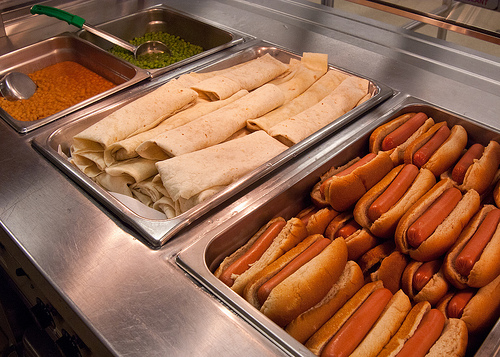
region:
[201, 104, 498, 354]
A lot of hot dogs.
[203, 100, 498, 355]
The hot dogs are in buns.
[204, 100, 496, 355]
The pan is made of metal.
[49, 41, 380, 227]
The wraps are made of bread.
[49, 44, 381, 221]
The wraps are white.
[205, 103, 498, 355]
The bread is brean.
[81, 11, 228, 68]
The peas are green.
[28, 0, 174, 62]
The spoon is large.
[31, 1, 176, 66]
The spoon is made of metal.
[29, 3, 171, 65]
The spoon handle is green.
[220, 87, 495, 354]
tray of hot dogs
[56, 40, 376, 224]
tray of burritos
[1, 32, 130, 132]
tray of pinto beans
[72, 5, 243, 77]
tray of peas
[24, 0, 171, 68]
serving spoon with green handle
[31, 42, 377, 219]
burritos with flour tortillas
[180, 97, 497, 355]
hot dogs in white buns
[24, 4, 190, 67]
metal serving spoon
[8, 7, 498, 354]
food in a hot buffet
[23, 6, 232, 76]
peas in a hot tray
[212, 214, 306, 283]
Hotdog in a bun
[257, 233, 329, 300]
A hot dog sitting in a bun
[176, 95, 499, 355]
A metal tray filled with hotdogs and buns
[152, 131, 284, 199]
A big burrito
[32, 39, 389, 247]
A metal tray filled with burritos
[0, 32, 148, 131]
A metal tray filled with baked beans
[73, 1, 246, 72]
A metal tray filled with green peas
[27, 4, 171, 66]
A large serving spoon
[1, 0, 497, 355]
A large metal table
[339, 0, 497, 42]
A glass backsplash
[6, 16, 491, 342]
food in metal steam trays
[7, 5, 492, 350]
large and small trays set into metal counter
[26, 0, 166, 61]
metal spoon with long and green handle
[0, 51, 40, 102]
back of utensil sitting in corner of tray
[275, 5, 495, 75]
ridges along edge of counter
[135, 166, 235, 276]
rounded corners inside trays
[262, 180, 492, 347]
plain hot dogs inside buns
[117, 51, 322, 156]
rolled and folded burritos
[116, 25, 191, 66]
olive-green peas in tray with spoon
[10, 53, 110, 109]
baked beans in sauce with utensil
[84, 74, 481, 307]
fast food at a buffett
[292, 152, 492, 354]
Hotdogs on buns on a buffet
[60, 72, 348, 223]
Burritos on a buffet table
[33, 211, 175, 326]
Buffet table is stainless steel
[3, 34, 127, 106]
Corn on buffet table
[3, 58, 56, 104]
Spoon in the corn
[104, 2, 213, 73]
Peas on the buffet table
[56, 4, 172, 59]
Green handled spoon in peas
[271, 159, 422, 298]
Plain hot dogs ready for eating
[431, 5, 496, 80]
Mirror on back of buffet table